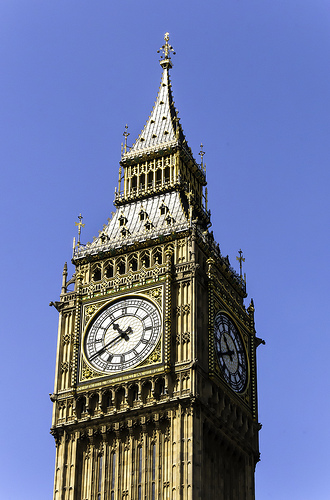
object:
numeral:
[119, 303, 128, 317]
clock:
[210, 304, 252, 400]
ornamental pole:
[76, 210, 82, 248]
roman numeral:
[132, 305, 140, 315]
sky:
[0, 0, 330, 499]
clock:
[80, 290, 164, 379]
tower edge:
[52, 435, 65, 499]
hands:
[86, 324, 132, 362]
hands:
[222, 333, 233, 362]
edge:
[186, 415, 198, 498]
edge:
[188, 265, 198, 407]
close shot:
[0, 0, 329, 499]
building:
[49, 29, 267, 498]